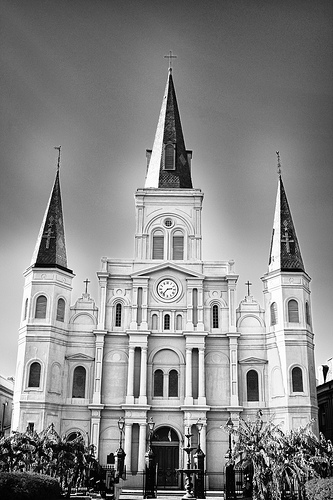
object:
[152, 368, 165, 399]
window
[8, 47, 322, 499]
building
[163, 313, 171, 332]
arch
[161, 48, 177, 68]
cross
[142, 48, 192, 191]
steeple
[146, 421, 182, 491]
door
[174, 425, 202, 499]
statue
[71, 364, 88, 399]
window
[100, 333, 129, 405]
wall